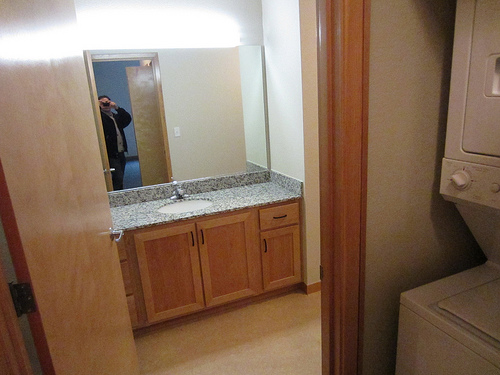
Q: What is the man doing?
A: Taking picture.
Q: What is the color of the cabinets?
A: Brown.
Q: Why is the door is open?
A: To take the picture of the bathroom.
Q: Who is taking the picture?
A: The man.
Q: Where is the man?
A: Outside the bathroom.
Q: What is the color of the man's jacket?
A: Black.